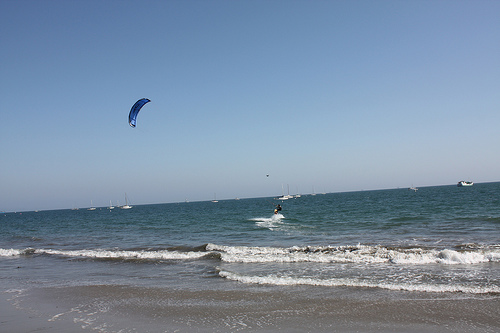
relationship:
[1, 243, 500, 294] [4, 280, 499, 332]
waves breaking on shore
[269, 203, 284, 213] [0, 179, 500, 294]
person parasailing in ocean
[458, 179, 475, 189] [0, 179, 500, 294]
boat in ocean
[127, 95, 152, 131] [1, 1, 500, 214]
sail in air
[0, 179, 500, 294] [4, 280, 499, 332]
ocean on shore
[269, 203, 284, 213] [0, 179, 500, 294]
person on ocean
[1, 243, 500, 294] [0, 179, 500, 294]
waves on ocean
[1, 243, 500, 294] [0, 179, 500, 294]
waves breaking on ocean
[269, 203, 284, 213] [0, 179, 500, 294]
person in ocean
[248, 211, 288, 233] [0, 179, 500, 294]
wave on ocean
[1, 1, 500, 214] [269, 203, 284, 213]
air above person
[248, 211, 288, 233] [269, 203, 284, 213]
wave behind person